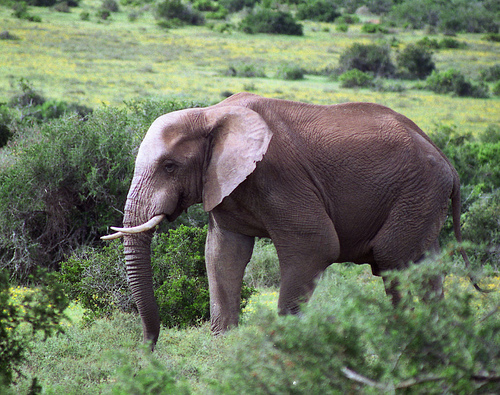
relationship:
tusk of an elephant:
[110, 211, 166, 233] [86, 93, 496, 368]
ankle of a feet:
[272, 296, 343, 315] [272, 313, 303, 325]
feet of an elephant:
[272, 313, 303, 325] [86, 93, 496, 368]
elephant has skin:
[86, 93, 496, 368] [279, 101, 428, 236]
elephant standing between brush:
[86, 93, 496, 368] [0, 1, 497, 391]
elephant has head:
[86, 93, 496, 368] [111, 115, 238, 349]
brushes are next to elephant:
[5, 76, 499, 391] [87, 75, 478, 369]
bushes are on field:
[419, 62, 467, 95] [1, 3, 491, 393]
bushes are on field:
[337, 40, 394, 81] [1, 3, 491, 393]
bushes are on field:
[292, 0, 342, 24] [1, 3, 491, 393]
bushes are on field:
[234, 7, 304, 37] [1, 3, 491, 393]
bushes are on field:
[152, 0, 209, 27] [1, 3, 491, 393]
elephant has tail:
[100, 91, 497, 343] [450, 167, 473, 268]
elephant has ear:
[100, 91, 497, 343] [199, 108, 274, 214]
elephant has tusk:
[100, 91, 497, 343] [110, 212, 161, 239]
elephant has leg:
[86, 93, 496, 368] [255, 211, 337, 335]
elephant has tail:
[100, 91, 497, 343] [451, 157, 475, 294]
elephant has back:
[86, 93, 496, 368] [281, 89, 418, 146]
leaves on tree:
[30, 123, 90, 164] [10, 92, 129, 269]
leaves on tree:
[30, 123, 90, 164] [389, 44, 441, 79]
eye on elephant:
[160, 154, 180, 176] [101, 99, 461, 365]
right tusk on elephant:
[98, 232, 129, 243] [86, 93, 496, 368]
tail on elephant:
[450, 167, 495, 297] [100, 91, 497, 343]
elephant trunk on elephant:
[122, 185, 160, 350] [100, 91, 497, 343]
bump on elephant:
[425, 152, 437, 167] [86, 93, 496, 368]